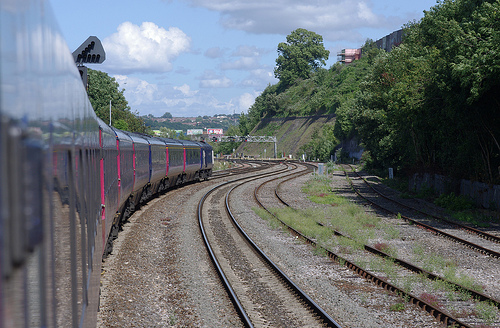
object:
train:
[0, 0, 213, 328]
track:
[93, 157, 256, 327]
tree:
[272, 28, 329, 84]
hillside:
[228, 24, 500, 209]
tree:
[346, 44, 423, 170]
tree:
[382, 56, 447, 174]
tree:
[445, 0, 499, 190]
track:
[338, 158, 499, 257]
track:
[196, 158, 347, 328]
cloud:
[196, 0, 387, 36]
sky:
[48, 1, 444, 118]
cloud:
[103, 18, 190, 72]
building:
[337, 49, 361, 66]